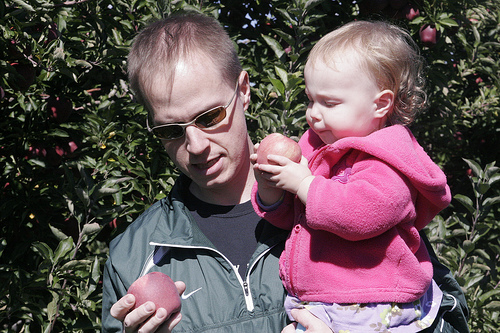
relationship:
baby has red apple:
[250, 15, 457, 329] [253, 129, 305, 184]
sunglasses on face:
[140, 100, 240, 144] [139, 52, 250, 193]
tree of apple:
[3, 4, 97, 325] [21, 97, 84, 165]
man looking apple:
[89, 5, 304, 332] [120, 267, 183, 331]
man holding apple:
[89, 5, 304, 332] [120, 267, 183, 331]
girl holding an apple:
[250, 15, 457, 329] [253, 129, 305, 184]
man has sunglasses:
[89, 5, 304, 332] [140, 100, 240, 144]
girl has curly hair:
[250, 15, 457, 329] [301, 16, 431, 151]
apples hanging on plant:
[405, 6, 441, 49] [410, 6, 499, 125]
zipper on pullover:
[233, 253, 260, 319] [96, 177, 302, 332]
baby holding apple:
[250, 15, 457, 329] [253, 129, 305, 184]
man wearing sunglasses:
[89, 5, 304, 332] [140, 100, 240, 144]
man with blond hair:
[89, 5, 304, 332] [120, 9, 265, 202]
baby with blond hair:
[250, 15, 457, 329] [301, 16, 431, 151]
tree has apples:
[3, 4, 97, 325] [47, 137, 83, 160]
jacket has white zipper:
[96, 177, 302, 332] [233, 253, 260, 319]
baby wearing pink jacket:
[250, 15, 457, 329] [241, 123, 454, 305]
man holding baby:
[89, 5, 304, 332] [250, 15, 457, 329]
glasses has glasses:
[140, 100, 240, 144] [140, 82, 237, 145]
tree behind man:
[3, 4, 97, 325] [89, 5, 304, 332]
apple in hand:
[253, 129, 305, 184] [255, 153, 310, 194]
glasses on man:
[140, 100, 240, 144] [89, 5, 304, 332]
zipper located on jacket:
[233, 253, 260, 319] [96, 177, 302, 332]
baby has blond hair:
[250, 15, 457, 329] [301, 16, 431, 151]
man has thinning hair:
[89, 5, 304, 332] [120, 9, 265, 202]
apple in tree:
[21, 97, 84, 165] [3, 4, 97, 325]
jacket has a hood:
[241, 123, 454, 305] [344, 118, 461, 236]